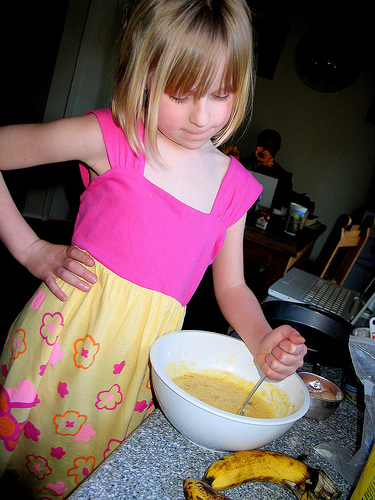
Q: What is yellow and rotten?
A: Banana.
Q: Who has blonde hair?
A: The girl.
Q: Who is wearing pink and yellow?
A: Little girl.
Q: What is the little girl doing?
A: Making food.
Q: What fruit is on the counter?
A: Banana.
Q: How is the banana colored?
A: Yellow and black.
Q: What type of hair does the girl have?
A: Blonde.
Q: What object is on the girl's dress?
A: Flowers.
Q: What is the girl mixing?
A: Batter.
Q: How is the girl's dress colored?
A: Yellow and pink.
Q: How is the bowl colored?
A: White.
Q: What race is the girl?
A: Caucasian.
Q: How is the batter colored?
A: Yellow.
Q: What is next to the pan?
A: Laptop.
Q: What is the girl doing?
A: Stirring.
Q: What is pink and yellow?
A: Dress.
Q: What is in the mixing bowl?
A: Cake mix.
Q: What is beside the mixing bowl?
A: Bananas.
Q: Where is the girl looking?
A: At the mix.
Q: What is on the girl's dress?
A: Flowers.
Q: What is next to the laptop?
A: A pan.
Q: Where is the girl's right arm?
A: On hip.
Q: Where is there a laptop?
A: On counter.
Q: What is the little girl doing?
A: Stirring.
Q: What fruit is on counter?
A: Bananas.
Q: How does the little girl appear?
A: Focused.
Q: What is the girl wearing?
A: Dress.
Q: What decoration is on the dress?
A: Flowers.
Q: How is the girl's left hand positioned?
A: In fist.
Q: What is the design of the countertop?
A: Speckled.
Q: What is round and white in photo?
A: Bowl.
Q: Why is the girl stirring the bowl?
A: The get the food ready.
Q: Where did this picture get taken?
A: It was taken in the kitchen.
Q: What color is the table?
A: The table is grey.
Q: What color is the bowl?
A: The bowl is white.